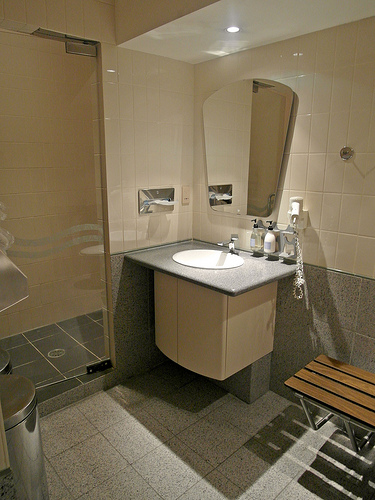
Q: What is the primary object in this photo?
A: A vanity.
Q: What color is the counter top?
A: Grey.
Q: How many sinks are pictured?
A: 1.